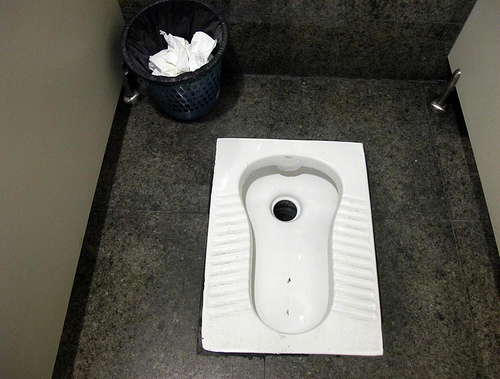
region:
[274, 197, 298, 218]
The hole in the urinal.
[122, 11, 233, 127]
The trash bin.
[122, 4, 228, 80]
The black bag in the trash bin.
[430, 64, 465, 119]
The silver pole on the right.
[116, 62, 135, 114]
The silver pole on the left.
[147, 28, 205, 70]
The toilet paper in the trash bin.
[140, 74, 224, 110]
The holes on the trash bin.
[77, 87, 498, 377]
The marble design of the floor.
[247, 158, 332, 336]
The base of the urinal.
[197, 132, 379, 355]
The design on the urinal structure.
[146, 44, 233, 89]
white towels in bin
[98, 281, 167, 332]
grey tile on floor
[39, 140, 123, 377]
black skirting board in room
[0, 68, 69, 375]
wall is off white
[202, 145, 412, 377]
white toilet like structure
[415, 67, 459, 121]
metal handle near wall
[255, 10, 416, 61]
grey and black wall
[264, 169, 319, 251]
hole in middle of toilet like structure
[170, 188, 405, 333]
textured sides of structure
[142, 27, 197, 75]
white paper in bin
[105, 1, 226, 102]
black bin in corner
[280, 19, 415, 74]
black wall behind bin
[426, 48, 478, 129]
silver object in corner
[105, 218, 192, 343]
floor is dark grey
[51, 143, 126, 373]
skirting board is black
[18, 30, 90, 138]
white wall near bin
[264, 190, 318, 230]
hole in center of apparatus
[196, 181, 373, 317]
textured sides of apparatus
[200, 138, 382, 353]
white toilet in ground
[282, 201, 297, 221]
hole in the toilet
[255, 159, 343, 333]
white base of toilet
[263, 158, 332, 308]
white bowl of toilet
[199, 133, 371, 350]
square base of toilet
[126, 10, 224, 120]
black trashcan on ground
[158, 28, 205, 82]
white paper in can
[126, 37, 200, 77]
toilet paper in trash can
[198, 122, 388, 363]
this is a toilet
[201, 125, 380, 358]
this is a white toilet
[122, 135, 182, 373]
this is the toilet floor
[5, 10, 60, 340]
this is the toilet wall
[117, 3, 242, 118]
this is the dustbin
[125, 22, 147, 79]
this is the black gabbage bin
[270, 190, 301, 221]
this is the toilet hole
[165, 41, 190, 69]
this is white in colour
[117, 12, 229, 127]
this is a plastic garbage bin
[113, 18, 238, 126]
waste basket with trash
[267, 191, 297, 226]
hole in the flush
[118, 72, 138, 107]
black and white handle on the wastebasket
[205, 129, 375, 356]
white flush on the floor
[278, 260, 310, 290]
water in the flush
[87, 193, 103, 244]
black border on the bottom of the wall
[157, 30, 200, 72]
paper in the waste bin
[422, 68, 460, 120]
silver pipe connected to the wall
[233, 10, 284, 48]
gray black wall in back of the waste bin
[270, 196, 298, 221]
dark black circle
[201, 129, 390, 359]
long white ceramic square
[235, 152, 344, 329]
long white ceramic oval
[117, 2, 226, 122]
short black trash can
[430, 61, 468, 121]
short silver object on floor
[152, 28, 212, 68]
white papers in trash can